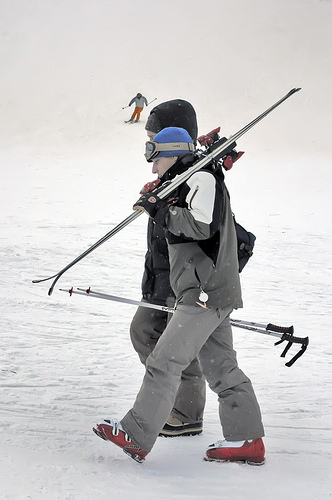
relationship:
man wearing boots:
[101, 131, 275, 472] [90, 410, 271, 472]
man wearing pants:
[101, 131, 275, 472] [128, 302, 263, 450]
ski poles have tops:
[57, 283, 312, 356] [56, 285, 92, 298]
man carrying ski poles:
[101, 131, 275, 472] [57, 283, 312, 356]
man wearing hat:
[101, 131, 275, 472] [151, 125, 193, 156]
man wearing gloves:
[101, 131, 275, 472] [133, 192, 164, 217]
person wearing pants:
[121, 90, 159, 131] [129, 105, 147, 122]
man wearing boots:
[135, 92, 250, 445] [162, 410, 204, 443]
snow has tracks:
[3, 4, 330, 499] [7, 242, 316, 456]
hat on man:
[151, 125, 193, 156] [101, 131, 275, 472]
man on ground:
[92, 126, 268, 470] [5, 3, 331, 499]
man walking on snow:
[92, 126, 268, 470] [3, 4, 330, 499]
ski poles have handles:
[57, 283, 312, 356] [260, 317, 312, 376]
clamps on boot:
[107, 419, 134, 442] [90, 415, 152, 468]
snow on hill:
[3, 4, 330, 499] [3, 4, 331, 211]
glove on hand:
[133, 192, 164, 217] [135, 190, 186, 226]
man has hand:
[101, 131, 275, 472] [135, 190, 186, 226]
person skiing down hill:
[121, 90, 159, 131] [3, 4, 331, 211]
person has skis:
[121, 90, 159, 131] [123, 115, 141, 129]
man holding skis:
[101, 131, 275, 472] [33, 73, 306, 320]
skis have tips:
[33, 73, 306, 320] [29, 276, 60, 297]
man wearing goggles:
[101, 131, 275, 472] [141, 139, 198, 158]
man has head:
[101, 131, 275, 472] [139, 127, 205, 189]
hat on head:
[151, 125, 193, 156] [139, 127, 205, 189]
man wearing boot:
[101, 131, 275, 472] [90, 415, 152, 468]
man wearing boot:
[101, 131, 275, 472] [199, 434, 269, 470]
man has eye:
[101, 131, 275, 472] [150, 155, 164, 167]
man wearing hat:
[135, 92, 250, 445] [148, 99, 201, 146]